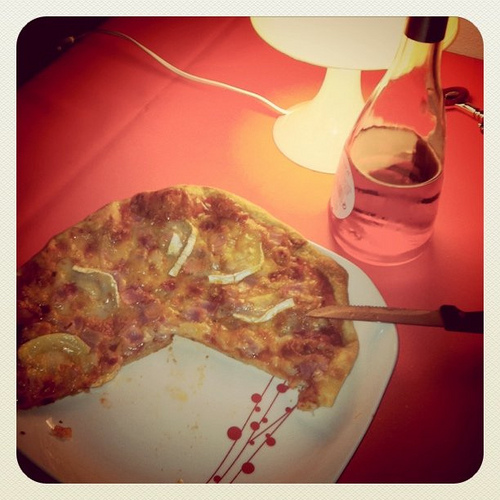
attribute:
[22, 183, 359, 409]
pizza — eaten, cheesy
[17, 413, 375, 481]
plate — square, white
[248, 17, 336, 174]
lamp — glowing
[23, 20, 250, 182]
table — red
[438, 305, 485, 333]
handle — black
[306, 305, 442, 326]
blade — serated, silver